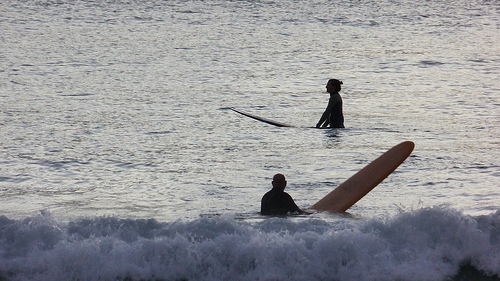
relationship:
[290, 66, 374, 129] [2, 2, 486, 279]
girl in water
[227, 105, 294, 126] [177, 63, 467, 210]
board in water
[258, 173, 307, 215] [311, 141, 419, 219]
man sitting on a surfboard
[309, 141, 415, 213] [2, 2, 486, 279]
board out of water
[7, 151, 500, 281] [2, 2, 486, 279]
wave in water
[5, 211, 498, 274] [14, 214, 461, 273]
spray of waves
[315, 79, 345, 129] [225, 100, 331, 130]
girl with surfboard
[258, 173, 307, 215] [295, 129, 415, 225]
man with surfboard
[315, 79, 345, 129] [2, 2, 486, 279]
girl in water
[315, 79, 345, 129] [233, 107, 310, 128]
girl with surfboard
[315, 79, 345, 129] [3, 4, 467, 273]
girl in ocean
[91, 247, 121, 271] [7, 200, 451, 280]
froth of wave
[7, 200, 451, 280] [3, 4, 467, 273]
wave in ocean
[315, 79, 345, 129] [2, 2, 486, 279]
girl standing in water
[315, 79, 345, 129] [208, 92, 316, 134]
girl with surfboard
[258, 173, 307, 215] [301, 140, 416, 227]
man holding surfboard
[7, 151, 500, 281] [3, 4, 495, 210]
wave of water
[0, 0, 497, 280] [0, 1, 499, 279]
photo was taken outdoors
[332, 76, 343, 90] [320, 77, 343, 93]
hair stands up off head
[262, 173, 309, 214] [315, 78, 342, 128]
man and woman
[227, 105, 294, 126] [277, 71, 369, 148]
board held by a woman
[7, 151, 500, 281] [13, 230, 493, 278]
wave moves to shore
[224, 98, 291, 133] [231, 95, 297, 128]
board up in front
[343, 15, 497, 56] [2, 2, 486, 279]
light reflecting off water